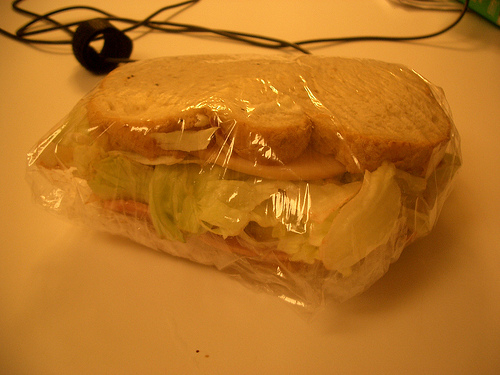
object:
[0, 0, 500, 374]
table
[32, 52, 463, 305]
sandwhich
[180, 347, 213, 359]
crumbs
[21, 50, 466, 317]
wrap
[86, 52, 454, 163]
bread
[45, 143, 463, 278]
green lettuce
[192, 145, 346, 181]
ham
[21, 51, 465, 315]
plastic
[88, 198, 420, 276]
bread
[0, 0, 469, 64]
cord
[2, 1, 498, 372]
surface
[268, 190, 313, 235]
light